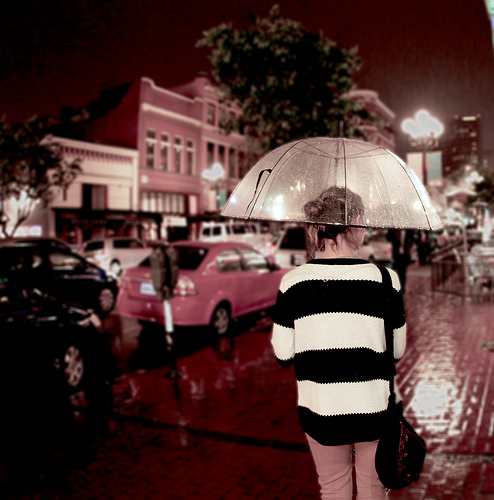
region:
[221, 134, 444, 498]
Young woman holding umbrella overhead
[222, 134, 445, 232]
See through umbrella over young woman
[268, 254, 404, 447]
Black and white sweater on young lady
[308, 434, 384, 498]
Pink pants on young lady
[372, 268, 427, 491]
Black purse carried by young lady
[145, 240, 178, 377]
Parking meter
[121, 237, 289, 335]
Pink parked car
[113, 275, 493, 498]
Wet red brick sidewalk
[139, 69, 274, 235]
Three story red brick building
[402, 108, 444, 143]
Light bulbs on street pole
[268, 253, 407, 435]
the woman is wearing a sweter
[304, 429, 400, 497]
the woman is wearing beige pants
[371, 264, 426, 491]
the woman is carrying a purse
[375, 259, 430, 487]
the purse is black in color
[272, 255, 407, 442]
the sweater is black and white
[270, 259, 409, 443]
the sweater has black stripes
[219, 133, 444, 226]
the woman is carrying and umbrella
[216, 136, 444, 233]
the umbrella is transparent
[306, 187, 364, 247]
the woman's hair is brown in color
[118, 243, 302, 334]
the car is red in color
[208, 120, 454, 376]
woman using a bubble umbrella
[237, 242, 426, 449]
woman wearing black and white sweater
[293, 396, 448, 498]
woman wearing pink pants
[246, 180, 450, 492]
woman carrying a black shoulder bag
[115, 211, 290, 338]
red car parked on the side of a street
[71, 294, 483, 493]
very wet brick sidewalk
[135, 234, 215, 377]
wet parking meter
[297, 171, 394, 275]
lady with long dark hair pulled up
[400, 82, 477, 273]
wet street lights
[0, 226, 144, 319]
black van driving down the road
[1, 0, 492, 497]
A night street scene.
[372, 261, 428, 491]
A black purse with a long strap.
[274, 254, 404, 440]
A black and white stripe sweater.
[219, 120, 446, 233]
A clear open umbrella.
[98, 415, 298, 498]
A wet red brick walk way.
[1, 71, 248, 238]
The pink looking buildings.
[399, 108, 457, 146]
The top of the street light.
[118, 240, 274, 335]
A pink parked car.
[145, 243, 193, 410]
A black parking meter with a white pole.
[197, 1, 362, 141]
The top of a tree.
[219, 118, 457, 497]
woman white and black sweater under clear umbrella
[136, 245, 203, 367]
parking meter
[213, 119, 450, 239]
clear umbrella with rain drops on it's surface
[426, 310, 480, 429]
wet pavement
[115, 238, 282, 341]
red car parked beside the road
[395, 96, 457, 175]
street lamp lights bright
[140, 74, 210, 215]
brick building with four large windows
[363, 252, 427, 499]
brown purse with long strap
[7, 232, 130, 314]
van driving down the road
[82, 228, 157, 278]
grey van parked on side of road